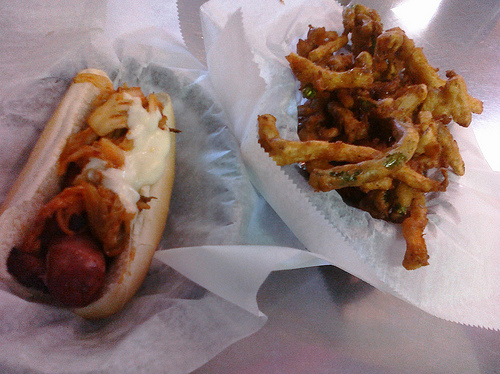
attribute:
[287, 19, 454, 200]
food — green, brown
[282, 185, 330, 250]
paper — white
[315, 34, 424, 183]
fried food — deep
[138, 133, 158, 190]
mayonnaise — white